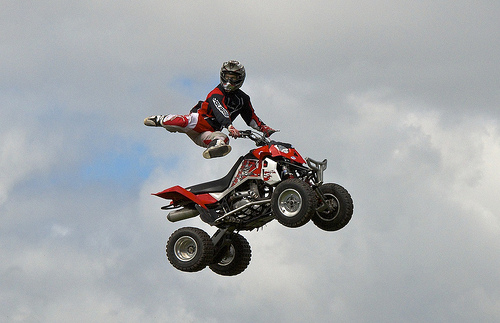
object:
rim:
[277, 188, 302, 218]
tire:
[269, 179, 317, 228]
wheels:
[165, 227, 216, 272]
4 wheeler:
[166, 178, 355, 277]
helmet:
[219, 60, 247, 93]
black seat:
[184, 155, 244, 195]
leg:
[162, 112, 199, 133]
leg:
[192, 130, 230, 149]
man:
[144, 60, 275, 159]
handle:
[263, 129, 279, 137]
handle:
[229, 130, 250, 138]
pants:
[162, 111, 229, 148]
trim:
[162, 115, 188, 128]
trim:
[202, 138, 213, 145]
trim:
[223, 137, 228, 144]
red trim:
[160, 83, 275, 147]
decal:
[229, 158, 276, 189]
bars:
[228, 130, 269, 146]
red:
[251, 144, 307, 164]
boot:
[202, 138, 232, 159]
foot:
[202, 145, 231, 159]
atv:
[151, 129, 354, 276]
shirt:
[188, 84, 265, 132]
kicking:
[144, 114, 188, 134]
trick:
[143, 60, 354, 277]